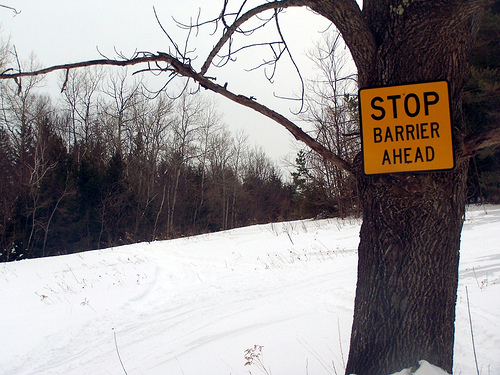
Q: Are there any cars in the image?
A: No, there are no cars.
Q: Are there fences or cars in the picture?
A: No, there are no cars or fences.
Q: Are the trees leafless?
A: Yes, the trees are leafless.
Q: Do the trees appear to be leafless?
A: Yes, the trees are leafless.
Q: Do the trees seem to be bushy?
A: No, the trees are leafless.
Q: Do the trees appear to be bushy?
A: No, the trees are leafless.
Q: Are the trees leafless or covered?
A: The trees are leafless.